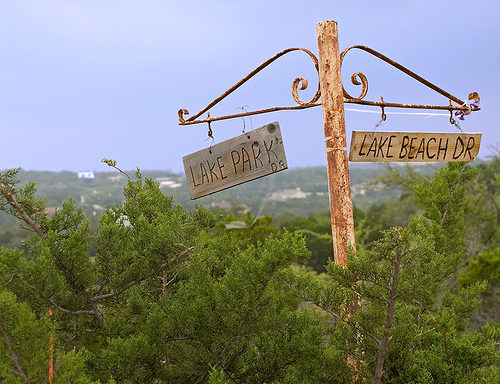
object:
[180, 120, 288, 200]
street sign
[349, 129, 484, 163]
street sign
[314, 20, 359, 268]
pole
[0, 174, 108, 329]
branches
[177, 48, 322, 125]
rod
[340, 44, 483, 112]
rod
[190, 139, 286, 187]
name of street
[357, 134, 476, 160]
name of street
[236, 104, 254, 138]
wire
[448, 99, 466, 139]
wire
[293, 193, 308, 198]
rocks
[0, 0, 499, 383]
background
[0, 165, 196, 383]
trees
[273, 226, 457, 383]
tree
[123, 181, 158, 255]
leaves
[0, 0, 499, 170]
sky